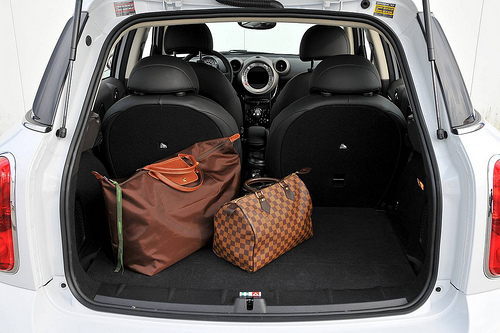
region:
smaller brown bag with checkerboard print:
[232, 177, 313, 255]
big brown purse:
[100, 136, 233, 258]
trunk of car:
[93, 139, 420, 295]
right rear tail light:
[487, 160, 498, 262]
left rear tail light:
[0, 159, 18, 276]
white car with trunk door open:
[1, 0, 488, 331]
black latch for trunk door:
[230, 289, 262, 316]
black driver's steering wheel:
[182, 49, 234, 88]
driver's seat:
[167, 23, 242, 148]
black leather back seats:
[106, 62, 391, 198]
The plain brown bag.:
[101, 142, 250, 277]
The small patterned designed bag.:
[225, 146, 320, 278]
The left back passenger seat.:
[116, 52, 246, 177]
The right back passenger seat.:
[277, 48, 414, 200]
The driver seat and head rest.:
[154, 25, 235, 102]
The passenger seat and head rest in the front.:
[286, 24, 365, 98]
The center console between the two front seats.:
[244, 119, 267, 152]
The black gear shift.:
[247, 98, 264, 117]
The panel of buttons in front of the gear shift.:
[243, 95, 269, 123]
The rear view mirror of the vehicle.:
[229, 15, 281, 30]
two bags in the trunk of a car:
[81, 128, 358, 290]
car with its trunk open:
[1, 1, 496, 331]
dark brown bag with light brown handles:
[85, 134, 239, 286]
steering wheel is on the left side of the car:
[183, 46, 239, 83]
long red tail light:
[479, 153, 499, 283]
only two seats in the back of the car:
[108, 48, 400, 208]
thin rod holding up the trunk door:
[415, 2, 446, 137]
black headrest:
[302, 56, 384, 108]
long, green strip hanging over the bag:
[109, 179, 131, 275]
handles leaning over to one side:
[241, 165, 291, 201]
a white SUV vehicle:
[7, 0, 498, 330]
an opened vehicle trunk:
[65, 11, 443, 318]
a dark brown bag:
[99, 132, 241, 279]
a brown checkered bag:
[214, 167, 314, 273]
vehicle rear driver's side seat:
[105, 62, 245, 198]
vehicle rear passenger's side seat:
[257, 57, 411, 197]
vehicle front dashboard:
[226, 54, 299, 98]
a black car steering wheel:
[181, 45, 235, 80]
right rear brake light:
[486, 152, 498, 275]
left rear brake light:
[0, 152, 18, 272]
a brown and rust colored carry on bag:
[218, 175, 328, 267]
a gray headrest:
[313, 49, 385, 101]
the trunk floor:
[318, 212, 398, 285]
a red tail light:
[0, 150, 18, 277]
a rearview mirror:
[234, 19, 281, 31]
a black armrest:
[246, 117, 267, 149]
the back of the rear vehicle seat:
[268, 97, 404, 182]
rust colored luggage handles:
[154, 156, 206, 191]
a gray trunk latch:
[233, 297, 271, 315]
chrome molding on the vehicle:
[25, 115, 49, 135]